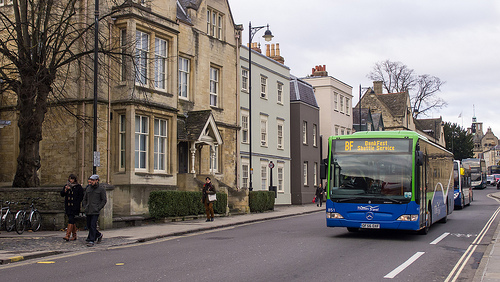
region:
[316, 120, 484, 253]
Blue and green bus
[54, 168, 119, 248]
Two people walking on the pavement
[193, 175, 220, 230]
Woman walking on the pavement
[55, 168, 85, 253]
Woman walking on the pavement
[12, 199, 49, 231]
Bicycle parked on the pavement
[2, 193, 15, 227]
Bicycle parked on the pavement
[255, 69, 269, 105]
Window to a building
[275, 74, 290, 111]
Window to a building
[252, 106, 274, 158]
Window to a building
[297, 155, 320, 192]
Window to a building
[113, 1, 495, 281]
a bus driving in a residential area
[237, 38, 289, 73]
chimneys on a building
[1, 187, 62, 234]
bicycles parked in front of a low wall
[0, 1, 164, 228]
tall bare tree behind wall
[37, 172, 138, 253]
two people walking together on sidewalk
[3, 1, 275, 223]
hedges in front of yellow residence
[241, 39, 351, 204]
dark building between two lighter buildings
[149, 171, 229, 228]
woman standing in front of a hedge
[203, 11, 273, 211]
street lamp at level with upper windows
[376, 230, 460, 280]
broken lines on road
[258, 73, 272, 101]
a window of a building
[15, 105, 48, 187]
the trunk of a tree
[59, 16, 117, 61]
the branches of a tree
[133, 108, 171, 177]
the windows of a building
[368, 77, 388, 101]
a chimney on a house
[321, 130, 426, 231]
the front of a bus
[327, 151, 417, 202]
the front window of a bus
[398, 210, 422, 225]
the head light of a bus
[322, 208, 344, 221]
the head light of a bus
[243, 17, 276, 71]
a street light on a pole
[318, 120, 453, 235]
the bus is blue and green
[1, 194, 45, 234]
two bikes beside each other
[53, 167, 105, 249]
two people walking down the street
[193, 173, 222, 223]
a person holding a white bag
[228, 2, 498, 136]
the sky is cloudy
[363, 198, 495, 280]
white lines on the road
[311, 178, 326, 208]
a person holding a red bag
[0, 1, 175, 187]
the tree is bare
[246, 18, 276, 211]
a tall street lamp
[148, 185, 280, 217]
hedges in front of the building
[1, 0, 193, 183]
large tree with no leaves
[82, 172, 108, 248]
man in a grey cap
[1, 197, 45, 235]
three parked black bicycles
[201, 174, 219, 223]
woman with a large white purse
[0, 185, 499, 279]
black top paved street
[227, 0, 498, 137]
cloudy grey overcast sky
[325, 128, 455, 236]
blue and green colored bus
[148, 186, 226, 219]
line of trimmed bushes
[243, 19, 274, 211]
very tall antique style lamppost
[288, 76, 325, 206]
squat dark brown building